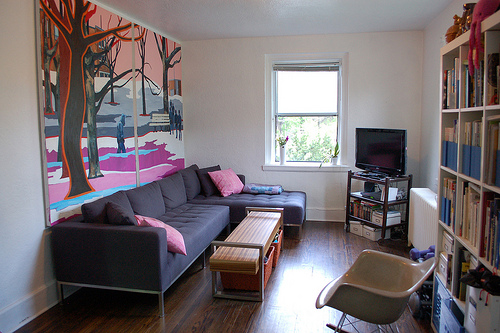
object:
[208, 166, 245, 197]
pillow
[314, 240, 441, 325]
chair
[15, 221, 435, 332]
floor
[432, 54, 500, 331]
books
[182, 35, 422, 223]
wall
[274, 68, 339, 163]
window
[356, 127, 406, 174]
tv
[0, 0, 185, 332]
wall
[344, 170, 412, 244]
shelfing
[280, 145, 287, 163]
vase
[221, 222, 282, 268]
boxes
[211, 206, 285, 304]
table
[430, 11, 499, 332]
bookcase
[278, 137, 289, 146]
flowers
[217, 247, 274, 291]
basket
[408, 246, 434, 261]
weights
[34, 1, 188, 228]
painting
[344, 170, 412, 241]
stand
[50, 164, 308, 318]
couch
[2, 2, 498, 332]
room